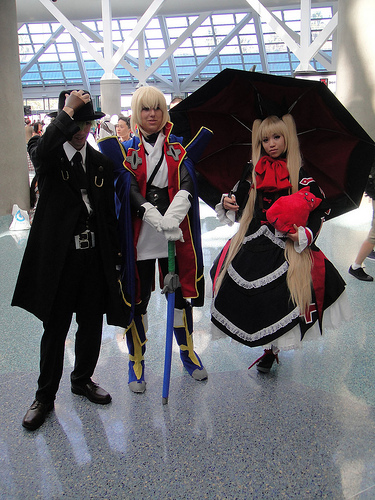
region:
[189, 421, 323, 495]
The floor is gray.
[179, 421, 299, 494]
The floor is glossy.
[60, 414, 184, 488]
Reflections can be seen on the floor.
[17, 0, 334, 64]
Braces for the ceiling are in the background.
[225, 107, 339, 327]
The girl has long hair.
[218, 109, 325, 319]
The hair is blonde.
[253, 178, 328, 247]
The girl is carrying a red animal.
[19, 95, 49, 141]
Other people can be seen in the background.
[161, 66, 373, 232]
The umbrella is large.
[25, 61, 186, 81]
The roof is blue.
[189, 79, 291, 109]
black large opened umbrella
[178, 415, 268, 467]
light blue specked floor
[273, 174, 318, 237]
red evil looking pikachu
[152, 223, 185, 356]
green and blue sword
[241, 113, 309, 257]
woman with long blonde ponytails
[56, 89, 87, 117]
man holding his black top hat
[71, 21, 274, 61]
white designed beams on ceiling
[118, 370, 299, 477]
shadow and reflection of group of people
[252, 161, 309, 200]
large red bow on neck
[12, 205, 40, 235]
blue and white plastic bag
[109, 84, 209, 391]
person wearing a costume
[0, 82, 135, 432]
person wearing a costume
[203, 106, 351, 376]
person wearing a costume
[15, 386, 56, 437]
a black leather shoe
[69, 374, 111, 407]
a black leather shoe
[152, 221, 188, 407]
a fake blue sword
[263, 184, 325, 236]
large red stuffed animal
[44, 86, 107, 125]
black hat on a head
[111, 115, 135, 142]
lady in a group of people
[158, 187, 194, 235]
a large white glove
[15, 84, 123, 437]
a man dressed up in a costume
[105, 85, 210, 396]
a man dressed up in a costume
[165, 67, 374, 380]
a woman dressed up in a costume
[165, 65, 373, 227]
a large black umbrella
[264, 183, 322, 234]
a red plush cat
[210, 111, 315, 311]
a woman with long blonde ponytails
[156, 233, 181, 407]
a blue and green plastic sword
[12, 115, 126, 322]
a black suit coat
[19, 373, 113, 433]
a pair of black shoes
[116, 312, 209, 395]
a pair of blue yellow and white boots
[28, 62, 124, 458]
a man in a costume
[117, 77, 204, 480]
a woman in a costume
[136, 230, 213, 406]
a fake sword for costume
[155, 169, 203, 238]
a woman wearing white gloves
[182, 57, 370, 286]
a woman holding an umbrella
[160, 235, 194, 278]
green handle for sword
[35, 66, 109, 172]
a man in a black hat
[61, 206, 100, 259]
a belt buckle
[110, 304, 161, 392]
yellow and blue boots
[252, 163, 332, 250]
a red stuffed animal